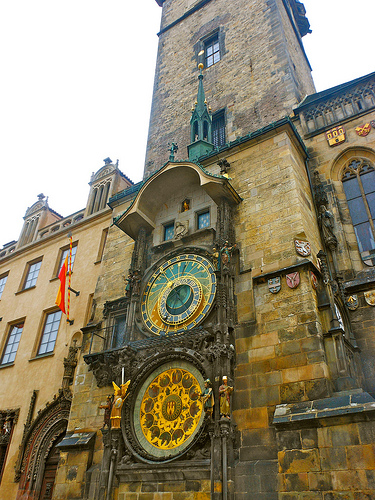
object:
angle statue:
[108, 376, 131, 429]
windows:
[0, 351, 12, 366]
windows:
[205, 45, 213, 57]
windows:
[42, 311, 53, 325]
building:
[0, 0, 374, 498]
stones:
[273, 130, 291, 145]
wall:
[53, 131, 337, 499]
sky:
[0, 0, 374, 240]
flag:
[54, 258, 67, 317]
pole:
[65, 234, 73, 327]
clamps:
[67, 285, 79, 296]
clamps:
[65, 315, 75, 325]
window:
[48, 318, 60, 333]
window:
[204, 53, 213, 68]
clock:
[139, 251, 218, 336]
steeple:
[185, 61, 216, 164]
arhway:
[12, 394, 73, 490]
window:
[22, 279, 32, 290]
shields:
[266, 276, 280, 294]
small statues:
[217, 372, 232, 420]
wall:
[0, 213, 116, 498]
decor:
[195, 377, 214, 421]